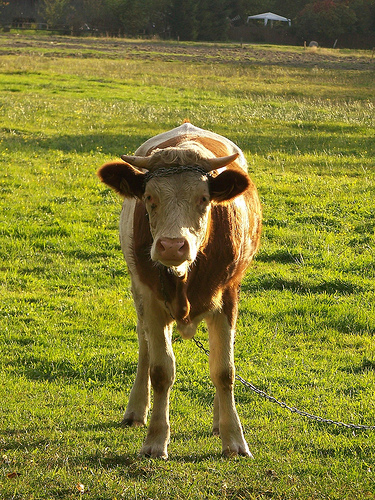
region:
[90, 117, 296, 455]
cow standing on the grass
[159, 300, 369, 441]
chain hanging down from the cow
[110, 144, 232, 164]
horns on top of the head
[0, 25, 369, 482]
green grass on the ground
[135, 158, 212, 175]
chain wrapped around the top of the head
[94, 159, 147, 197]
brown fur on the ear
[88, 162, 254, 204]
ears sticking out of the sides of the head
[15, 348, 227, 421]
faint shadow on the grass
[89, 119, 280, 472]
brown and white cow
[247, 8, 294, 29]
white tent in the distance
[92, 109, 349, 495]
this is a steer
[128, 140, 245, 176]
horns on a steer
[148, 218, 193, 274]
pink nose of steer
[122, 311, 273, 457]
front white cow legs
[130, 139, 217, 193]
chain around steer head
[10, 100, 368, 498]
the field is grass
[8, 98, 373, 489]
the field is green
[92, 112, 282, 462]
a cow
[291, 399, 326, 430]
a metal chain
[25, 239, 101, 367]
a field of green grass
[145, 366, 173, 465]
right front leg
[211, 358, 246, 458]
left leg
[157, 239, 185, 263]
the cows nose is pink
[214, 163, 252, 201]
left ear is brown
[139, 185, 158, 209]
right eye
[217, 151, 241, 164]
the left horn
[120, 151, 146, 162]
the right horn on the cow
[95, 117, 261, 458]
the cow standing on the grass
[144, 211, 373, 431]
the chain connected to the cow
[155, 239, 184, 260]
the nose on the cow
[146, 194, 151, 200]
the eye on the cow's face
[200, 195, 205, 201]
the eye on the cow's face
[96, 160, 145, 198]
the ear on the cow's head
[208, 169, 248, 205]
the ear on the cow's head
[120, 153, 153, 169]
the horn on the cow's head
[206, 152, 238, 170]
the horn on the cow's head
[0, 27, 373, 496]
the green grass in the large area